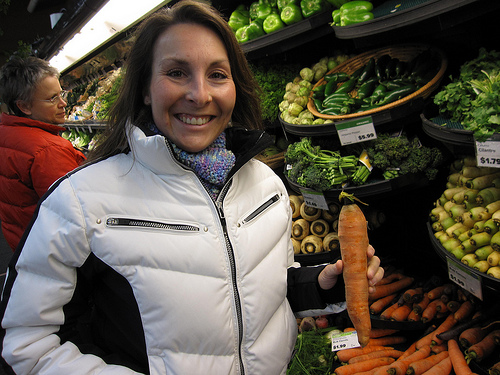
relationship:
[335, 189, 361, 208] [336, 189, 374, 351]
top of carrot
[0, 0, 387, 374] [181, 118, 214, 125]
woman has teeth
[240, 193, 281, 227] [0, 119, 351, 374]
zipper on jacket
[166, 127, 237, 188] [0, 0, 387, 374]
scarf on woman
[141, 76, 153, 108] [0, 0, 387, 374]
ear on woman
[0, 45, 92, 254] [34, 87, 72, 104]
lady has glasses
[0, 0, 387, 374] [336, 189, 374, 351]
woman has carrot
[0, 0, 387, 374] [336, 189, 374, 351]
woman has a carrot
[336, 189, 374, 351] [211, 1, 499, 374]
carrot in stand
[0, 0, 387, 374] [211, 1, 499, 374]
woman at stand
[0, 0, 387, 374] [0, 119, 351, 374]
woman has jacket